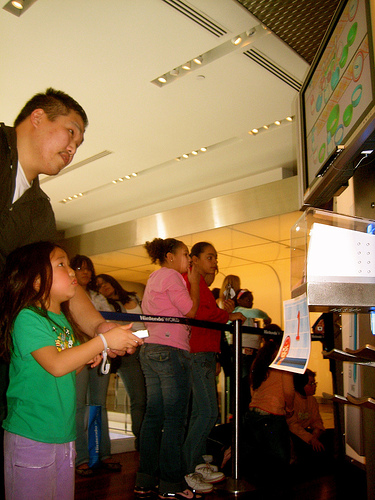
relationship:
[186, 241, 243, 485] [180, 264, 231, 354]
girl wearing jacket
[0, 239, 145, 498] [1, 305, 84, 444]
girl wearing shirt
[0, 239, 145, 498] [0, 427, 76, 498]
girl wearing pants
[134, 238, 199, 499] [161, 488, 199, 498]
girl wearing sneaker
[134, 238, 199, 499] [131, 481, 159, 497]
girl wearing sneaker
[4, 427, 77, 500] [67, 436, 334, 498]
pants sitting on floor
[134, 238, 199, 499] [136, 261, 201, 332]
girl wearing shirt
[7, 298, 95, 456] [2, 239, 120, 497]
shirt on girl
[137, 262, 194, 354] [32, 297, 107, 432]
shirt on girl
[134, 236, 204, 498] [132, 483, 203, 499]
girl wearing shoes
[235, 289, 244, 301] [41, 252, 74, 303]
headband on girl's head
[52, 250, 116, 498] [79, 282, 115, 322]
woman wearing shirt